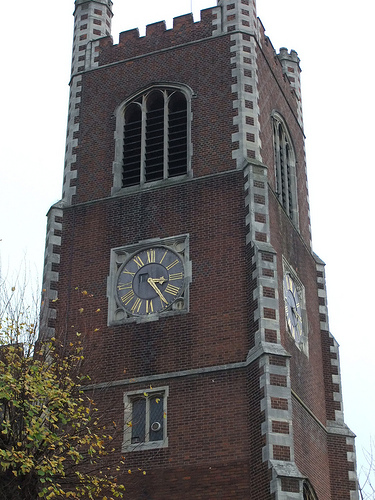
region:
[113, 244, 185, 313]
large clock on tall brick building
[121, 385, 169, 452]
window on large brick building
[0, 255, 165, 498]
tree in front of brick building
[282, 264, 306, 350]
gray and gold clock on side of building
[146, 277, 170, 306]
clock hands pointing to 3:24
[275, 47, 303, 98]
corner tower on large brick building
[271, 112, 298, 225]
large window on on brick building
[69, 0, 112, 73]
corner tower on brick building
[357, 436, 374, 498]
bare tree on side of building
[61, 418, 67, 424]
single green leaf on tree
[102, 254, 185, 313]
the clock's hands are gold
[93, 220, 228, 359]
the clock's hands are gold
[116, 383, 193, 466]
the window pane is gray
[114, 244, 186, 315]
clock with golden numerals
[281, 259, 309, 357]
clock with golden numerals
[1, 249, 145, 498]
bush growing near clock tower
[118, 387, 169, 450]
window in clock tower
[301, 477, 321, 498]
window in clock tower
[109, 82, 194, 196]
vent in clock tower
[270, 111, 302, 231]
vent in clock tower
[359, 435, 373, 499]
tree branch near clock tower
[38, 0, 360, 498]
brick clock tower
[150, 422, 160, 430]
circular object on window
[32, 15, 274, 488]
this is taken outdoors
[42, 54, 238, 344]
this is a building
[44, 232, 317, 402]
this is a clocktower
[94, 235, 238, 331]
this is a clock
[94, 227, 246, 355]
the clock is black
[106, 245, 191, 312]
the arms of the clock are gold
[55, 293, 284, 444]
the building is gothic style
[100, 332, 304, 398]
the buliding is made of bricks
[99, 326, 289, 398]
the bricks are red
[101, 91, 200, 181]
the window has a vent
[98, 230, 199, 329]
a huge clock on a building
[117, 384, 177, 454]
a window of a building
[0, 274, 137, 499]
tree branches with yellow leaves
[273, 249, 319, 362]
a huge clock on a building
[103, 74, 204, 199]
a huge window on the building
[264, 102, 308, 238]
huge window on a building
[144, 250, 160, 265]
roman numeral letters on a clock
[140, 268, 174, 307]
the hour and minute hands of a clock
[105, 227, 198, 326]
a circular clock on a building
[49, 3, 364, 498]
a tall brick building